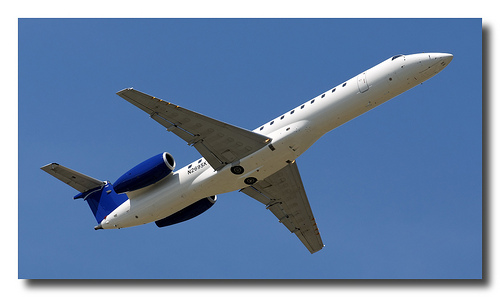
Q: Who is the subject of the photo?
A: The plane.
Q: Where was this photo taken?
A: In the sky.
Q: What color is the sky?
A: Light blue.